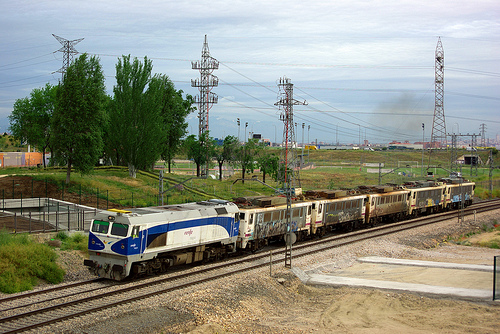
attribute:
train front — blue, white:
[83, 196, 244, 254]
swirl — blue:
[111, 217, 241, 253]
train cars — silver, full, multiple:
[236, 179, 482, 249]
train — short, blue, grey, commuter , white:
[83, 175, 476, 280]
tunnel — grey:
[3, 193, 117, 229]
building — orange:
[0, 149, 52, 170]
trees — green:
[12, 54, 199, 173]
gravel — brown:
[0, 201, 498, 332]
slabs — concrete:
[307, 271, 498, 305]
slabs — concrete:
[358, 251, 498, 270]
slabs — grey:
[301, 252, 500, 300]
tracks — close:
[0, 197, 499, 331]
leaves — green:
[14, 101, 52, 121]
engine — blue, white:
[84, 196, 240, 278]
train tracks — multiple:
[0, 194, 500, 332]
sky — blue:
[2, 0, 499, 152]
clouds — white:
[127, 2, 498, 146]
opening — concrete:
[2, 197, 120, 238]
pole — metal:
[288, 180, 294, 268]